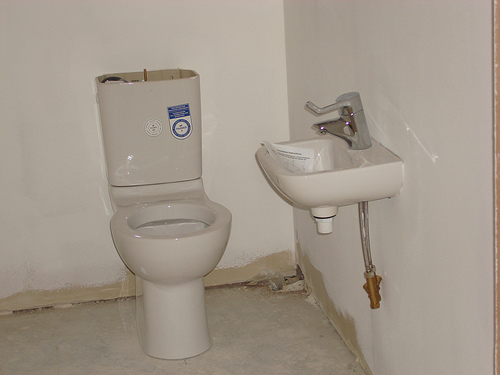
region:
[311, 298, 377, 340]
water damage on ground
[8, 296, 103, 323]
cracked line on the edge of wall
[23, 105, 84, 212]
white walls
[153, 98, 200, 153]
blue and white label on toilet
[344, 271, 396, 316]
gold copper on bathroom sink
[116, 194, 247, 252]
large round toilet bowl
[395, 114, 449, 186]
small scrape on wall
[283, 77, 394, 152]
silver faucet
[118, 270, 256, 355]
large white base on toilet seat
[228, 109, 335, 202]
white paper in bathroom sink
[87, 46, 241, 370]
the toilet is white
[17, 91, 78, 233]
the wall is white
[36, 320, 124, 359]
the ground is white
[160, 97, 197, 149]
the sticker is blue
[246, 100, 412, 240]
the sink is white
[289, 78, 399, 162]
the metal is silver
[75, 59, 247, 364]
the toilet is narrow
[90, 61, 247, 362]
the toilet is open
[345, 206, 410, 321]
the pipes are metal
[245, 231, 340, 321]
the corner is broken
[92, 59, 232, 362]
A white toilet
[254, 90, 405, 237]
A white sink with silver fixtures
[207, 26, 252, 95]
A white bathroom wall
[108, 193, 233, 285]
a white toilet bowl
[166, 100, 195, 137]
a blue sticker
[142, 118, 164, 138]
a white round sticker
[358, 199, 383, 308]
a pipe leading to the sink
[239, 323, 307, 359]
a dingy bathroom floor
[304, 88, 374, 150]
A silver faucet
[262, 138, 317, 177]
a white piece of paper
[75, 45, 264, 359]
Toilet against the wall.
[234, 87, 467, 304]
Sink on the wall.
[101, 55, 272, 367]
Toilet with no lid.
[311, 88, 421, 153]
Faucet on the sink.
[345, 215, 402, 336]
Pipe on the wall.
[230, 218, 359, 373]
Water damage on the floor.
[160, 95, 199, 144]
Label on the toilet.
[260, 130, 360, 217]
Paper in the sink.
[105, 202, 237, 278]
Empty toilet bowl.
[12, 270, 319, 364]
Crack in the seam of the wall.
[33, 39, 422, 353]
working on a new bathroom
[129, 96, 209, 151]
labels on toilet tank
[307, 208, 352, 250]
bottom drain outlet from sink.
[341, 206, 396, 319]
incoming water lines to sink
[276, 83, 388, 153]
sink faucet with single handled water control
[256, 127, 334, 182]
information regarding bathroom sink lies in basin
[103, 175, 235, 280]
toilet bowl without seat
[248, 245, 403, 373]
bottom of wall awaits floor molding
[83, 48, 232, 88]
Float ball barely shows above tank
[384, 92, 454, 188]
A smudge of white on the white wall